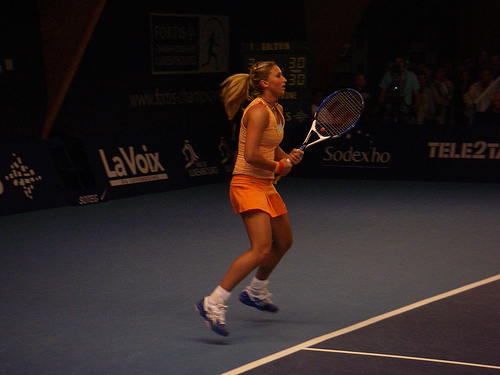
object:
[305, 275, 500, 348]
lines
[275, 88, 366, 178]
tennis racket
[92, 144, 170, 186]
advertisement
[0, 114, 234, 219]
wall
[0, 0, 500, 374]
air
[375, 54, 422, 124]
man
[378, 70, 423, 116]
shirt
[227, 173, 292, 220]
orange skirt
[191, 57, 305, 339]
woman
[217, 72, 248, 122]
ponytail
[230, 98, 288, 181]
shirt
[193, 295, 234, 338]
shoe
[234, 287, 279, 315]
shoe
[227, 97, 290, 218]
tennis outfit